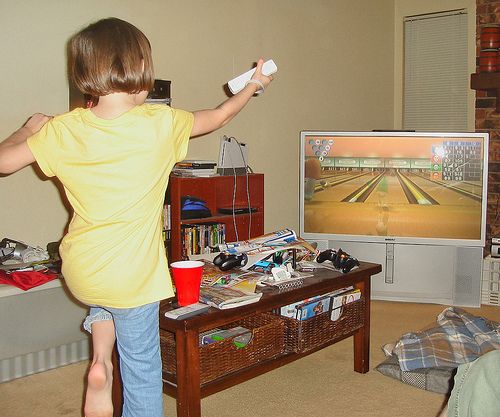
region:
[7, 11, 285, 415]
Little girl playing a Wii game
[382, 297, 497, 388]
Blue, white and beige plaid blanket on the floor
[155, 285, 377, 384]
Wicker drawers inside coffee table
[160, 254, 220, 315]
Red plastic cup in coffee table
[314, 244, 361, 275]
Black video came controller on coffee table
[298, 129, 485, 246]
Wii bowling game on TV screen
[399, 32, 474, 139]
White mini blinds covering window behind TV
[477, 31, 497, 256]
Brick wall next to window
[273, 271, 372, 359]
Video game cases inside wicker drawer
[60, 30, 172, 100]
Little girl with a bob haircut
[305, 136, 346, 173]
this is a tv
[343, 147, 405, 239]
the tv is on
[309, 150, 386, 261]
the tv is large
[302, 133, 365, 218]
the tv has a game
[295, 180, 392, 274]
the tv is silver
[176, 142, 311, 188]
this is a console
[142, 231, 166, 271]
this is a shirt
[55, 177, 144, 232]
the shirt is yellow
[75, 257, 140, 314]
this is a child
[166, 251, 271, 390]
the cup is red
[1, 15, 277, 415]
a girl playing an interactive video game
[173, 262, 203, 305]
a red plastic cup on a table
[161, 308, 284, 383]
a brown wicker basket on a table shelf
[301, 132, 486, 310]
a big silver TV in a living room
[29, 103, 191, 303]
a girl wearing a yellow shirt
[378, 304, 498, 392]
a plaid blanket on the floor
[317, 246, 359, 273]
a black video game controller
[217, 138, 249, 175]
a modem on a wooden bookshelf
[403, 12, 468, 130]
white horizontal blinds on a window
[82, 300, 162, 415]
girl wearing light blue jeans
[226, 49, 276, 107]
the game remote in the girls hand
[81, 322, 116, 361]
the bare skin on her leg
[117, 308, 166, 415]
the jean pant leg on the girl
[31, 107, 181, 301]
the yellow tee shirt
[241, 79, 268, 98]
the wristband on the girl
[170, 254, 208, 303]
the red plastic cup on the coffee table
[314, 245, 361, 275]
the black controller on the table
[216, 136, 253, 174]
the game system on the shelf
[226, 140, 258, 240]
the chords hanging down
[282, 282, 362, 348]
the movies in the wicker basket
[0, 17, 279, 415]
Young girl playing Wii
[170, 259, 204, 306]
Red plastic Solo cup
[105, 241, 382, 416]
Wooden coffee table on carpet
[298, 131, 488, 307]
Silver flat screen television set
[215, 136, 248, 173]
White Wii gaming system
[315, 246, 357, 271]
Black Playstation remote control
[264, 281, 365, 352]
Wicker drawer holding DVDs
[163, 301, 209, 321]
White and grey remote control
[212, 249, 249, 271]
Black Playstation remote control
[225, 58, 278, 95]
White Wii remote control